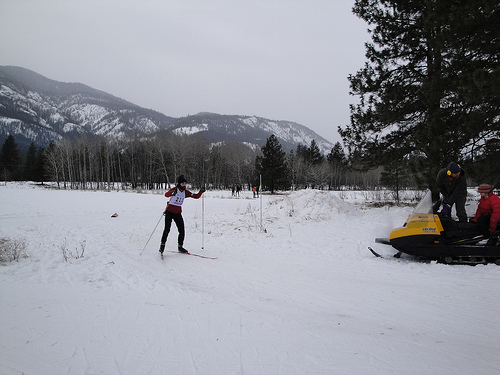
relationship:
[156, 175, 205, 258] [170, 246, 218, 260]
person wearing skis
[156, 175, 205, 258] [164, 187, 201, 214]
person wearing red shirt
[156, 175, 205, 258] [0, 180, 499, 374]
person standing on snow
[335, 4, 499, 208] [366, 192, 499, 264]
tree behind snowmobile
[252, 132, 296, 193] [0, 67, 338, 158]
tree in front of mountain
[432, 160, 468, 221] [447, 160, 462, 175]
person wearing yellow earmuffs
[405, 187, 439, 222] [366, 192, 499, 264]
glass on snowmobile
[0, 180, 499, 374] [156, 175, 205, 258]
snow beneath person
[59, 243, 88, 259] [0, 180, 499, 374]
branch on snow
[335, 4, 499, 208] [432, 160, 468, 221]
tree behind person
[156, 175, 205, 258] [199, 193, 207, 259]
person holding ski pole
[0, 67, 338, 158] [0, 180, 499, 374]
mountain behind snow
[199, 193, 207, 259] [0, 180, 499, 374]
ski pole in snow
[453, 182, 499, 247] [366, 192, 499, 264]
person sitting on snowmobile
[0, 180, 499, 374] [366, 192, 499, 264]
snow beneath snowmobile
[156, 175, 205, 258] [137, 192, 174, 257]
person holding ski pole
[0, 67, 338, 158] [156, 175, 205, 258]
mountain behind person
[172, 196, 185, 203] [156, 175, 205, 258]
number on person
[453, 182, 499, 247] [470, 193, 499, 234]
person wearing red coat